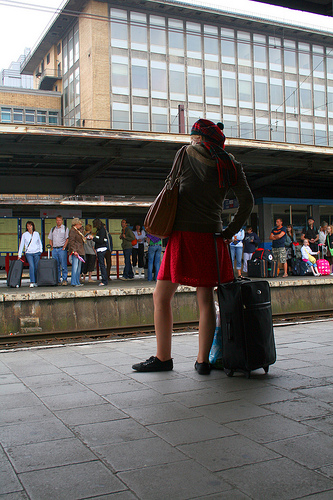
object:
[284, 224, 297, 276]
woman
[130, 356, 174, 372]
black shoes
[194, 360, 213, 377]
black shoes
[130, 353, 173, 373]
foot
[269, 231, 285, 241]
arms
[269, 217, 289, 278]
man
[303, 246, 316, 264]
bag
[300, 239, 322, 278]
girl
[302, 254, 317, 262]
lap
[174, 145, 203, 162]
shoulder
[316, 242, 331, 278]
suitcase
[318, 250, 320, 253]
hand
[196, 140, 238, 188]
scarf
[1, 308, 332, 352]
tracks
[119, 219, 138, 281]
man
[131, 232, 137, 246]
backpack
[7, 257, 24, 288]
luggage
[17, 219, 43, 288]
woman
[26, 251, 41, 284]
jeans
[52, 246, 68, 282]
jeans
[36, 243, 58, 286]
luggage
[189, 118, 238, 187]
beanie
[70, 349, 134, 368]
cement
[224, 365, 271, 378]
wheels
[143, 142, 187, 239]
bag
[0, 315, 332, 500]
platform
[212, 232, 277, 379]
bag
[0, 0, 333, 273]
building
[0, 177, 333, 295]
station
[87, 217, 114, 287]
people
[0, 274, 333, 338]
platform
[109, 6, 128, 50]
window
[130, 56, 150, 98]
window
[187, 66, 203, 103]
window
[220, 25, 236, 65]
window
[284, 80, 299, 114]
window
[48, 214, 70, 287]
man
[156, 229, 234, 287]
skirt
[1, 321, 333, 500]
sidewalk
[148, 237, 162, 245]
shirt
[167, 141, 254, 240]
top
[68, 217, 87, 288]
people